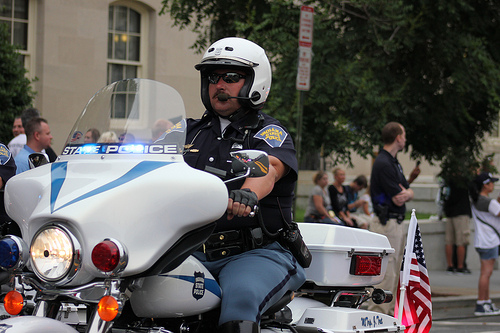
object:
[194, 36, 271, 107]
helmet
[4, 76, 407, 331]
motorcycle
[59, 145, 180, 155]
logo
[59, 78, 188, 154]
windshield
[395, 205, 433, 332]
flag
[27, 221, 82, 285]
headlight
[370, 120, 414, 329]
man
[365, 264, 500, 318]
curb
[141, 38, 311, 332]
policeman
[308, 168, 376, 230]
people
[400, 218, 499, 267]
wall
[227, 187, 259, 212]
gloves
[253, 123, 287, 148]
patch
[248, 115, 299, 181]
sleeve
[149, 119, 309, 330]
uniform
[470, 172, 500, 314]
female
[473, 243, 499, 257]
shorts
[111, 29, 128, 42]
light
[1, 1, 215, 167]
building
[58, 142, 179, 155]
sign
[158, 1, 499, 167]
tree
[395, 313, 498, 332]
street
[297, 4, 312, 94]
signs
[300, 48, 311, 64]
no parking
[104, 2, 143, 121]
window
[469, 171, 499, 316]
woman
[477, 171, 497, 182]
hat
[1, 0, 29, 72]
window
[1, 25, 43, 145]
tree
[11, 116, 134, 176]
people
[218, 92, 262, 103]
speaker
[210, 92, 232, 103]
mouth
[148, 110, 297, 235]
shirt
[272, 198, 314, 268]
walkie talkie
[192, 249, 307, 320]
pants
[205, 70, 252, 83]
sunglasses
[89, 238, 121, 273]
light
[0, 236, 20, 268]
light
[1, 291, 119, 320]
lights